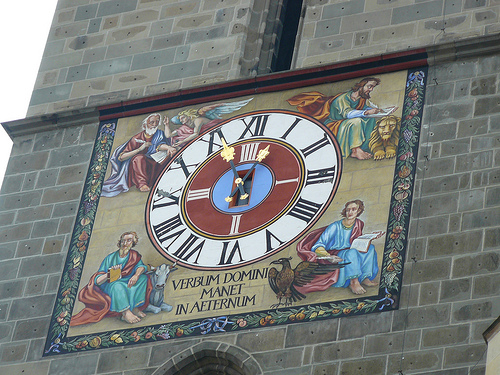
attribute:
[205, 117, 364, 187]
numerals — roman, sideways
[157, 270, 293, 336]
words — french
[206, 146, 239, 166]
hand — minute, here, short, hour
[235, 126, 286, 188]
hand — hour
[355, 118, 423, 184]
lion — golden, laying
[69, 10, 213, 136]
building — brick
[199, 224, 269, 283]
numeral — 6, black, brick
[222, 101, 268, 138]
numeral — 12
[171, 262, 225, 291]
word — verbum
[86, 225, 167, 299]
man — sitting, old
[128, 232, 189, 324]
cow — layin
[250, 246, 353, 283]
bird — pointing, showing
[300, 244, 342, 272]
wings — pointing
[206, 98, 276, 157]
numberal — 12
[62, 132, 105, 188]
design — painted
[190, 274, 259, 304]
manet — on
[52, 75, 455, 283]
wall — here, stone, old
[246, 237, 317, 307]
drawing — man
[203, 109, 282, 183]
hands — gold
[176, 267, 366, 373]
phrase — latin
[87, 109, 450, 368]
figure — sitting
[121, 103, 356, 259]
pictures — painted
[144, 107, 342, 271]
clock — beautiful, here, white